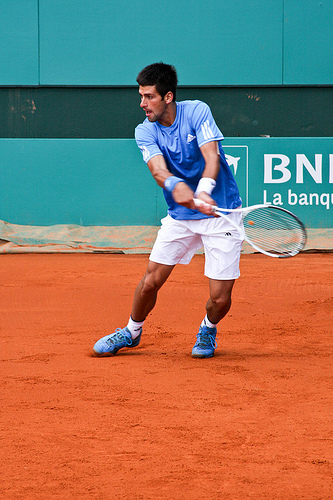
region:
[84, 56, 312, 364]
a tennis player swinging his racket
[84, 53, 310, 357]
a tennis player in a blue shirt swinging his racket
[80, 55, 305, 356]
a tennis player with blue shoes swinging his racket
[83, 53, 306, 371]
a tennis player wearing white shorts swinging his racket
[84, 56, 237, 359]
a tennis player wearing a blue shirt and blue shoes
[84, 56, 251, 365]
a tennis player wearing white shorts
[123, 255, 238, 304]
the quadriceps of a tennis player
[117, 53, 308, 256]
a tennis player wearing a blue shirt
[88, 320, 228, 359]
a pair of blue tennis shoes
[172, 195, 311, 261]
a tennis racket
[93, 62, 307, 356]
a tennis player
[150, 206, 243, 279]
man wearing white shorts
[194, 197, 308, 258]
a white and gray tennis racket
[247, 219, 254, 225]
a small orange ball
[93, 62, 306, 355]
man ready to hit a ball with a tennis racket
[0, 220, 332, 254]
a dirty tarp on the ground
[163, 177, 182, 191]
man wearing a blue wristband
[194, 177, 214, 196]
a white wristband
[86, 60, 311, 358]
The man is holding a tennis racket.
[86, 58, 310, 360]
The man is wearing blue tennis shoes.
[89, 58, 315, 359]
Thw man's shirt is blue and white.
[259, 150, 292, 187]
The letter is white.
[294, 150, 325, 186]
The letter is white.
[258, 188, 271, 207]
The letter is white.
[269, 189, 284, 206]
The letter is white.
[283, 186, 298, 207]
The letter is white.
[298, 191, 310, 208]
The letter is white.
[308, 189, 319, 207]
The letter is white.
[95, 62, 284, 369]
the man on the court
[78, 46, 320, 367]
the man swinging the racquet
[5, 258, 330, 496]
the court is clay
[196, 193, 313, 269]
the racquet is white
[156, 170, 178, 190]
blue band on the wrist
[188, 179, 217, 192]
white band on the wrist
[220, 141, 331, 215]
the ad on the wall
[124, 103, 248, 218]
the man wearing blue t shirt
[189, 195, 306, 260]
a black and white tennis racket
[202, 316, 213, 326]
a man's white sock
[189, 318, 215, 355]
a blue tennis shoe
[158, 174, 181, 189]
a blue wristband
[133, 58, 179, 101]
a man's short cut black hair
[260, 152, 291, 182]
a large white capital letter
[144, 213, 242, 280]
a man's white shorts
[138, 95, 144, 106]
the nose of a man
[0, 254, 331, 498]
part of a tennis court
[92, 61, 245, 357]
Black haired tennis player.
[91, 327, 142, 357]
A tennis players right blue shoe.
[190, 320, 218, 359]
A tennis players left blue shoe.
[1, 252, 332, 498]
Orange colored dirt ground.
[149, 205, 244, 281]
White pair of tennis shorts.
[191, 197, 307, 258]
Mostly white tennis racket.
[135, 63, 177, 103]
Black hair on a man.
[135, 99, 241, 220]
Blue t-shirt on a tennis player.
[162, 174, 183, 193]
A blue wrist band.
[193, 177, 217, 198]
A white wristband on a wrist.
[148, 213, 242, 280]
the shorts are white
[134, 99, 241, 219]
the shirt is blue and white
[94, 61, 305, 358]
the man is holding a tennis racket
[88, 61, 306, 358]
the man is wearing wristbands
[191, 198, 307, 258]
the tennis racket is white